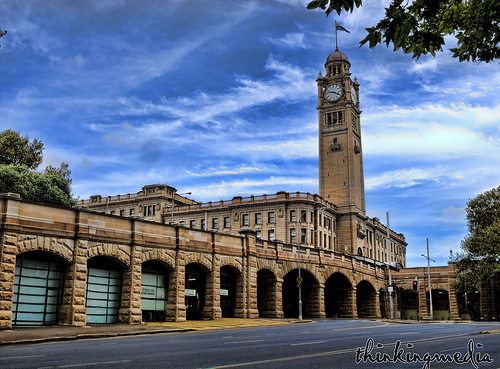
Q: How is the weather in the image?
A: It is cloudy.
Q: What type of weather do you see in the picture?
A: It is cloudy.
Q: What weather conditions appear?
A: It is cloudy.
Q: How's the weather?
A: It is cloudy.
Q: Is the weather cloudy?
A: Yes, it is cloudy.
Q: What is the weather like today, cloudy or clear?
A: It is cloudy.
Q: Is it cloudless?
A: No, it is cloudy.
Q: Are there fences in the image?
A: No, there are no fences.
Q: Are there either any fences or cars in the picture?
A: No, there are no fences or cars.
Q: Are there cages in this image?
A: No, there are no cages.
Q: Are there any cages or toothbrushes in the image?
A: No, there are no cages or toothbrushes.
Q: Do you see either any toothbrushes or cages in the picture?
A: No, there are no cages or toothbrushes.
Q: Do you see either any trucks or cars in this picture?
A: No, there are no cars or trucks.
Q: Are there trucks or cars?
A: No, there are no cars or trucks.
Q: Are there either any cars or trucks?
A: No, there are no cars or trucks.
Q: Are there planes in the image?
A: No, there are no planes.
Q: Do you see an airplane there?
A: No, there are no airplanes.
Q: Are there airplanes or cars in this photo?
A: No, there are no airplanes or cars.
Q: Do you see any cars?
A: No, there are no cars.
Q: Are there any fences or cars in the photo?
A: No, there are no cars or fences.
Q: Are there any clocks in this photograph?
A: Yes, there is a clock.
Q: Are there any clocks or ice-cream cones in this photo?
A: Yes, there is a clock.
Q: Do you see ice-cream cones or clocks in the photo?
A: Yes, there is a clock.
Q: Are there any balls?
A: No, there are no balls.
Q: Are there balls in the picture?
A: No, there are no balls.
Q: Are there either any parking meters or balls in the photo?
A: No, there are no balls or parking meters.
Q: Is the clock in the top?
A: Yes, the clock is in the top of the image.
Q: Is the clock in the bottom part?
A: No, the clock is in the top of the image.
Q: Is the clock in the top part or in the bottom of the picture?
A: The clock is in the top of the image.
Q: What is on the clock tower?
A: The clock is on the clock tower.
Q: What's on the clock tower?
A: The clock is on the clock tower.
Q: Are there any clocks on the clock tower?
A: Yes, there is a clock on the clock tower.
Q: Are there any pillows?
A: No, there are no pillows.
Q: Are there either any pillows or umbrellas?
A: No, there are no pillows or umbrellas.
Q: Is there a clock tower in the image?
A: Yes, there is a clock tower.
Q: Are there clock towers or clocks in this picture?
A: Yes, there is a clock tower.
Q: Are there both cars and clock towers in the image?
A: No, there is a clock tower but no cars.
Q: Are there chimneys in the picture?
A: No, there are no chimneys.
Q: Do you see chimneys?
A: No, there are no chimneys.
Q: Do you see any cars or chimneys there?
A: No, there are no chimneys or cars.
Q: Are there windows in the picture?
A: Yes, there are windows.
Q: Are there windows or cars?
A: Yes, there are windows.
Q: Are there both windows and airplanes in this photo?
A: No, there are windows but no airplanes.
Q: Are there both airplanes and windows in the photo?
A: No, there are windows but no airplanes.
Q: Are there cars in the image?
A: No, there are no cars.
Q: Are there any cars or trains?
A: No, there are no cars or trains.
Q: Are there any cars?
A: No, there are no cars.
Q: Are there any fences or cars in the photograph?
A: No, there are no cars or fences.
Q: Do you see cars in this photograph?
A: No, there are no cars.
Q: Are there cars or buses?
A: No, there are no cars or buses.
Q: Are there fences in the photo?
A: No, there are no fences.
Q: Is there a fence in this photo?
A: No, there are no fences.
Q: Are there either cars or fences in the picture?
A: No, there are no fences or cars.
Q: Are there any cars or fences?
A: No, there are no fences or cars.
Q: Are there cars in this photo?
A: No, there are no cars.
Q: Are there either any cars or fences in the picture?
A: No, there are no cars or fences.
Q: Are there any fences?
A: No, there are no fences.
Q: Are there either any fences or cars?
A: No, there are no fences or cars.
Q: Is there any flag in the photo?
A: Yes, there is a flag.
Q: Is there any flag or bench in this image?
A: Yes, there is a flag.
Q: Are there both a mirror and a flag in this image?
A: No, there is a flag but no mirrors.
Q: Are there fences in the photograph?
A: No, there are no fences.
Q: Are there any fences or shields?
A: No, there are no fences or shields.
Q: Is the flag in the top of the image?
A: Yes, the flag is in the top of the image.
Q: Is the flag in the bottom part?
A: No, the flag is in the top of the image.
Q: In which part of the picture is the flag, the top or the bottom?
A: The flag is in the top of the image.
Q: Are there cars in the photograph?
A: No, there are no cars.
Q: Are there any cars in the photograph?
A: No, there are no cars.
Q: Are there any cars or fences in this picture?
A: No, there are no cars or fences.